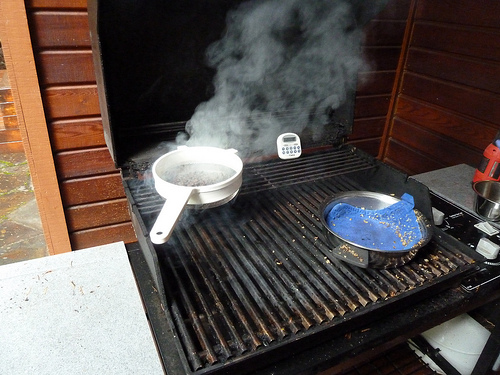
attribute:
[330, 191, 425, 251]
holder — pot, dirty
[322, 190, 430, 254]
bowl — stainless, steel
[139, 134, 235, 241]
pan — camping, white, plastic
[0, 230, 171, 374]
board — plastic, white, cutting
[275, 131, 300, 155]
timer — kitchen, small, white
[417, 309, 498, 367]
container — white, plastic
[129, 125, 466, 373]
grill — smoke over , timer over 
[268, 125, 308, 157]
timer — white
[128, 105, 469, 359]
grill — strainer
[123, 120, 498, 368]
grill — square , outdoor 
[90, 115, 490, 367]
grill — black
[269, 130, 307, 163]
white timer — small , white 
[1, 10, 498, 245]
wooden wall — brown 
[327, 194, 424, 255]
blue item — blue 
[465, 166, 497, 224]
silver bowl — silver 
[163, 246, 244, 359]
metal rail — black 